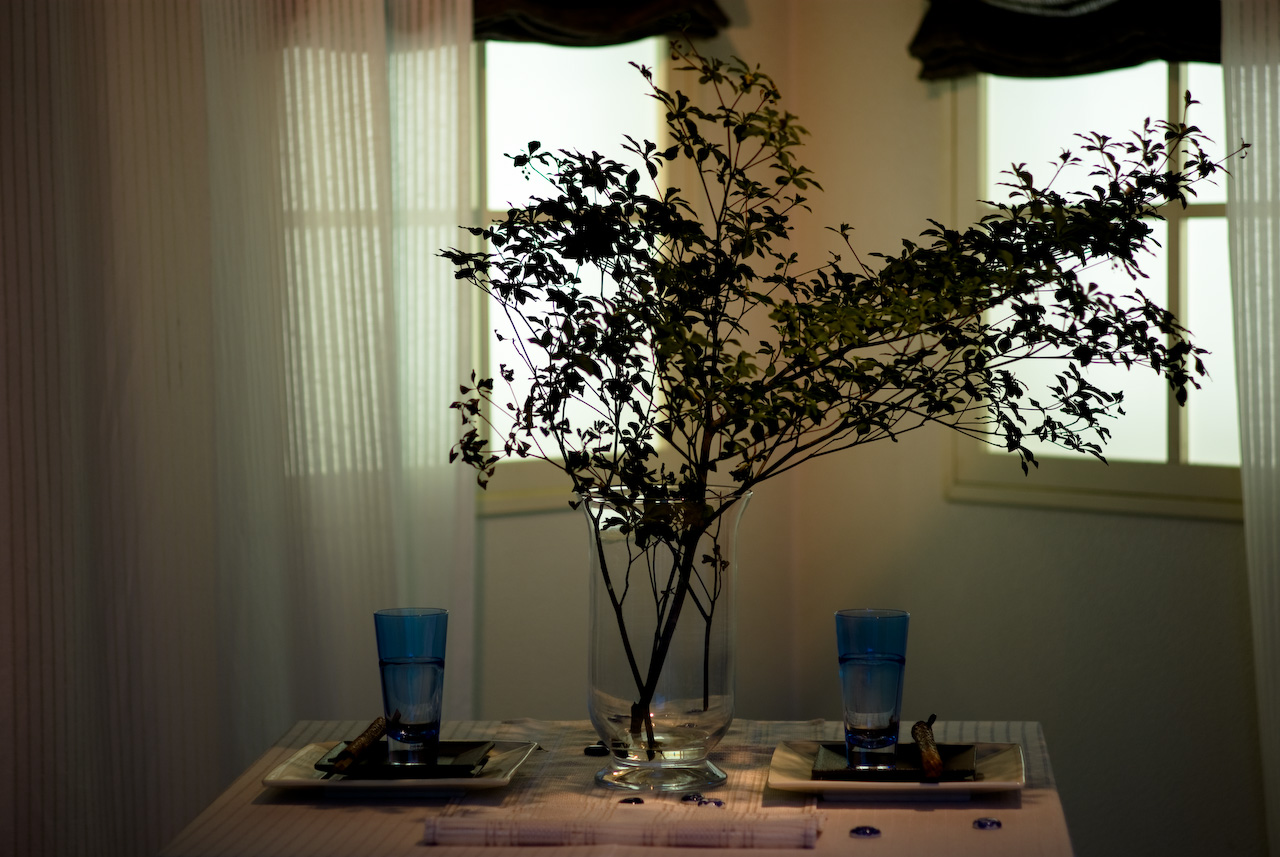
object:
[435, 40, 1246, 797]
branch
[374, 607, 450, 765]
cup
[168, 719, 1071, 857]
table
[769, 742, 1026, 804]
plate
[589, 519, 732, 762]
water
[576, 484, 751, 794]
vase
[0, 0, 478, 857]
curtain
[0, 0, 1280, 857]
dining room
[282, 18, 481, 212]
pane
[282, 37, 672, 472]
window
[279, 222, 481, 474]
pane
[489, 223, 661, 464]
pane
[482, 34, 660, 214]
pane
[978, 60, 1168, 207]
pane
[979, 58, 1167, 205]
window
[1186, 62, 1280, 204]
pane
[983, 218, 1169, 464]
pane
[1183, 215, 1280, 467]
pane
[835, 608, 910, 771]
pane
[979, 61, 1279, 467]
pane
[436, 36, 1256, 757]
stem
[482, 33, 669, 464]
glass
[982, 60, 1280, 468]
glass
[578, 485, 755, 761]
stem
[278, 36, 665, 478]
stem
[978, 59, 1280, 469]
stem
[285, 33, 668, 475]
wall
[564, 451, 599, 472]
leaf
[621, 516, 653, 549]
leaf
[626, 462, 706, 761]
stem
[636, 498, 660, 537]
leaf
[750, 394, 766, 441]
leaf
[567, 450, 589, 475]
leaf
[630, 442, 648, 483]
leaf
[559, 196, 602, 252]
leaf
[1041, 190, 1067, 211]
leaf